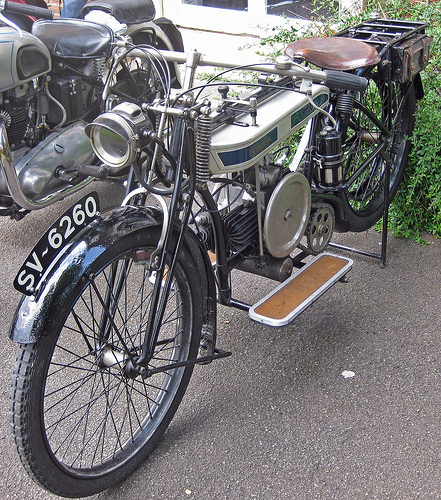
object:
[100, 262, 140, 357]
spoke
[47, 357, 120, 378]
spoke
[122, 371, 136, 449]
spoke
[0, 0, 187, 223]
bike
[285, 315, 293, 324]
silver boarder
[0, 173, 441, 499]
ground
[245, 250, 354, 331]
step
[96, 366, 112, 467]
spoke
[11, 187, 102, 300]
license plate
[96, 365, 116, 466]
spoke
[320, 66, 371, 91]
handle bar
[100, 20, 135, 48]
handle bar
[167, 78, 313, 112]
wire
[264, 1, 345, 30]
window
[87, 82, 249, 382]
frame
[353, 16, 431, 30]
spot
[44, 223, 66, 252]
numbers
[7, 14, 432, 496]
bike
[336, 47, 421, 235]
rubber wheel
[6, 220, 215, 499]
rubber wheel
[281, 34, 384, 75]
seat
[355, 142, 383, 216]
spokes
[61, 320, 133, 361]
spoke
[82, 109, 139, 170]
light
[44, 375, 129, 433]
spoke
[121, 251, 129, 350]
spoke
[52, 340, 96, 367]
spoke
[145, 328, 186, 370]
spoke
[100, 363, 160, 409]
spoke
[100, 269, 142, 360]
spoke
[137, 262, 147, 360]
spoke